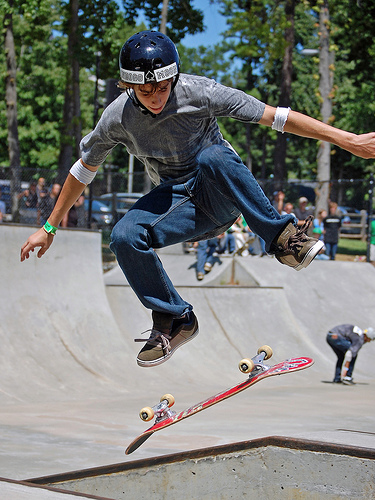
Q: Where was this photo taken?
A: Skatepark.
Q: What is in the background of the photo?
A: Trees.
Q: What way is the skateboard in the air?
A: Upside down.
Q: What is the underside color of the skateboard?
A: Red.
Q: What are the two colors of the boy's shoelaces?
A: White and brown.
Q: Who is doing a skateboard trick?
A: A boy.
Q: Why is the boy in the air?
A: Doing trick.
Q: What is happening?
A: Skateboarding.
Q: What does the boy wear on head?
A: A helmet.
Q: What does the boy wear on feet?
A: Brown shoes.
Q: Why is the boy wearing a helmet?
A: To protect himself from a head injury.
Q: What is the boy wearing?
A: A grey t-shirt and a pair of bluejeans.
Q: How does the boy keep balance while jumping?
A: By spreading his hands.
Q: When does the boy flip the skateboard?
A: When doing tricks.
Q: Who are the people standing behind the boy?
A: The spectators.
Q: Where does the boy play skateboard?
A: At a skatepark.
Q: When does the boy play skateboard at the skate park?
A: When the park is not too crowded.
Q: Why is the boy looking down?
A: To better control the skateboard.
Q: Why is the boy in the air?
A: Tricks.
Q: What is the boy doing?
A: Skateboarding.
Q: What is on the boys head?
A: Helmet.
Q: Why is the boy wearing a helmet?
A: Safety.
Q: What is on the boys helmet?
A: Sticker.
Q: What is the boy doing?
A: Skateboard tricks.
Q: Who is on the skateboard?
A: A boy.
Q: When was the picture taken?
A: Daytime.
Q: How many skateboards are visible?
A: One.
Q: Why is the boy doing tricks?
A: For fun.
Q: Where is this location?
A: Skatepark.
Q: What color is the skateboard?
A: Red.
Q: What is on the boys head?
A: Helmet.